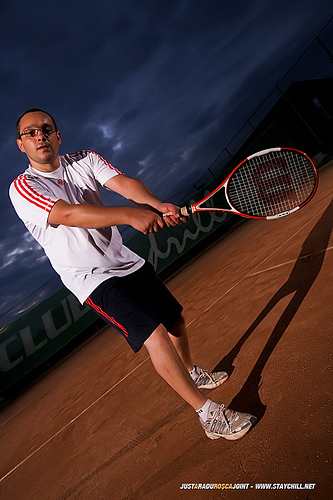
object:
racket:
[154, 144, 318, 225]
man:
[7, 94, 257, 442]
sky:
[4, 5, 307, 274]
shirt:
[1, 153, 146, 311]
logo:
[252, 157, 294, 210]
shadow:
[219, 206, 333, 414]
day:
[2, 8, 330, 495]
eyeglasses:
[17, 127, 57, 139]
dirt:
[21, 367, 151, 483]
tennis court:
[0, 203, 332, 496]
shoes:
[187, 356, 258, 442]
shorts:
[84, 260, 184, 355]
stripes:
[81, 293, 126, 337]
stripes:
[11, 177, 55, 211]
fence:
[187, 75, 331, 221]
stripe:
[204, 254, 295, 303]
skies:
[56, 17, 209, 106]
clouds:
[93, 109, 192, 169]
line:
[49, 372, 126, 441]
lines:
[211, 402, 229, 420]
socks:
[187, 367, 213, 423]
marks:
[90, 399, 170, 471]